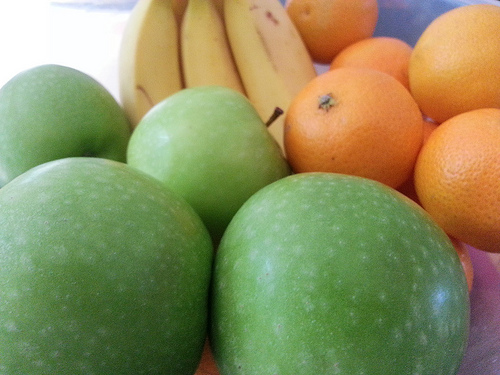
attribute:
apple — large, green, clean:
[127, 85, 297, 235]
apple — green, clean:
[210, 171, 472, 374]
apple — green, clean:
[0, 157, 216, 374]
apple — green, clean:
[2, 63, 130, 187]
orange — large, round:
[282, 66, 422, 189]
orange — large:
[413, 106, 499, 253]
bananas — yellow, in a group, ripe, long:
[118, 1, 319, 159]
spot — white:
[37, 190, 50, 202]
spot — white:
[119, 192, 131, 201]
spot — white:
[73, 189, 83, 197]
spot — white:
[15, 338, 41, 357]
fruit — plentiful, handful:
[1, 0, 498, 374]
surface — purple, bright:
[1, 0, 499, 374]